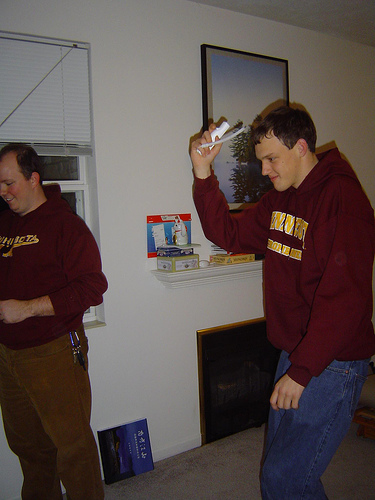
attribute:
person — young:
[181, 95, 373, 500]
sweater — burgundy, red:
[187, 144, 374, 392]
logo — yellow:
[261, 210, 310, 266]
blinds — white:
[1, 35, 96, 154]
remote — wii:
[197, 119, 246, 162]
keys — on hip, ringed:
[68, 330, 90, 374]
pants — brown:
[1, 324, 109, 500]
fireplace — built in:
[184, 306, 297, 452]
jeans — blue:
[252, 344, 374, 499]